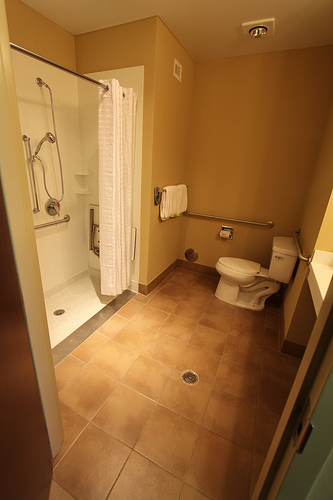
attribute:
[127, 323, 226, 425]
floor — brown, tiled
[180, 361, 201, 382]
drain — silver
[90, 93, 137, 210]
showercurtain — white, waffled, textured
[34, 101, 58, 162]
showerfaucet — silver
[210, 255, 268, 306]
toilet — white, porcelain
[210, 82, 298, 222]
wall — brown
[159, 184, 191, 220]
bathtowels — white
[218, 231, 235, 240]
toiletpaper — white, roll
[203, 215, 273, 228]
handle — silver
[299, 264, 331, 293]
countertop — white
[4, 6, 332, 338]
bathroom — clean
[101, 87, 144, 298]
curtain — white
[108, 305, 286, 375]
ceramicfloor — brown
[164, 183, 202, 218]
towels — white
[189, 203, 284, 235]
safetyhandrails — grey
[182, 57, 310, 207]
walls — mustard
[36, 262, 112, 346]
showerfloor — white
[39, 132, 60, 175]
showernozzle — handheld, metal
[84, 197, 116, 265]
showerseat — folddown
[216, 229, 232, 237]
rollpaper — white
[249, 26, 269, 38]
edging — black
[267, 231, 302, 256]
tankcover — white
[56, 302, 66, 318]
showerdarin — showerdrain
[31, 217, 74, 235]
showercurtain rod — metal